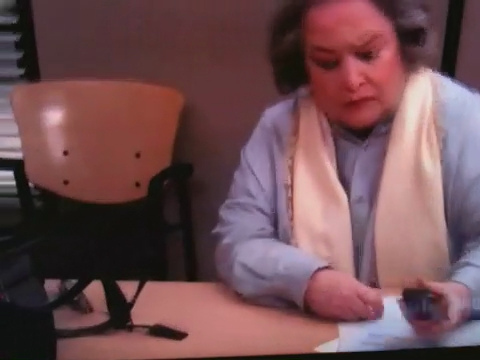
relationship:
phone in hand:
[402, 286, 448, 322] [397, 279, 475, 339]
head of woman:
[301, 1, 407, 129] [210, 1, 480, 337]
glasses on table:
[59, 277, 95, 316] [44, 279, 338, 360]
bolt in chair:
[63, 149, 70, 156] [6, 78, 197, 281]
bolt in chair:
[134, 153, 143, 159] [6, 78, 197, 281]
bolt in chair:
[134, 181, 141, 189] [6, 78, 197, 281]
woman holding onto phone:
[210, 1, 480, 337] [402, 286, 448, 322]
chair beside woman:
[6, 78, 197, 281] [210, 1, 480, 337]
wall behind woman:
[32, 1, 268, 280] [210, 1, 480, 337]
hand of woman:
[308, 266, 383, 325] [210, 1, 480, 337]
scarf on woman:
[286, 93, 351, 274] [210, 1, 480, 337]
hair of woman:
[372, 1, 429, 48] [210, 1, 480, 337]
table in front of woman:
[44, 279, 338, 360] [210, 1, 480, 337]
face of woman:
[311, 33, 393, 110] [210, 1, 480, 337]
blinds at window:
[1, 12, 18, 28] [1, 1, 31, 189]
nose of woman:
[343, 59, 365, 93] [210, 1, 480, 337]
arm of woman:
[212, 115, 331, 317] [210, 1, 480, 337]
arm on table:
[212, 115, 331, 317] [44, 279, 338, 360]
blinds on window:
[1, 51, 23, 63] [1, 1, 31, 189]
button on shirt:
[354, 194, 363, 203] [211, 70, 480, 317]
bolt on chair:
[64, 179, 69, 185] [6, 78, 197, 281]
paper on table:
[316, 319, 480, 359] [44, 279, 338, 360]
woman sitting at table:
[210, 1, 480, 337] [44, 279, 338, 360]